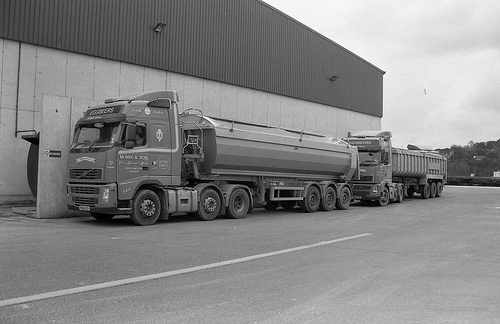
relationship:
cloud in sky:
[262, 0, 499, 150] [261, 1, 497, 150]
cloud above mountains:
[262, 0, 499, 150] [453, 144, 499, 174]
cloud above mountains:
[262, 0, 499, 150] [434, 141, 498, 188]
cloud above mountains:
[262, 0, 499, 150] [416, 132, 498, 179]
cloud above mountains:
[262, 0, 499, 150] [445, 136, 497, 177]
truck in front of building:
[65, 85, 357, 230] [2, 0, 386, 202]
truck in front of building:
[336, 129, 448, 204] [2, 0, 386, 202]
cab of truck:
[63, 91, 177, 219] [65, 85, 357, 230]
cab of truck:
[346, 132, 389, 202] [360, 135, 447, 201]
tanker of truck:
[177, 106, 361, 183] [65, 85, 357, 230]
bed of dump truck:
[394, 172, 445, 186] [346, 132, 451, 213]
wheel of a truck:
[129, 186, 162, 226] [65, 85, 357, 230]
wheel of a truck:
[197, 185, 220, 223] [65, 85, 357, 230]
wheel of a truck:
[229, 188, 251, 218] [65, 85, 357, 230]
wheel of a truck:
[300, 182, 322, 213] [65, 85, 357, 230]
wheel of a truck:
[322, 184, 337, 210] [65, 85, 357, 230]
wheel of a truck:
[197, 185, 220, 223] [68, 91, 355, 247]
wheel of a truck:
[337, 178, 364, 214] [70, 69, 418, 298]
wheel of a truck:
[377, 186, 392, 206] [348, 117, 445, 196]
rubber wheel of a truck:
[396, 182, 406, 200] [336, 129, 448, 204]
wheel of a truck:
[422, 183, 429, 198] [345, 130, 446, 205]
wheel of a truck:
[430, 181, 439, 195] [359, 124, 449, 213]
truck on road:
[336, 129, 449, 205] [2, 187, 498, 319]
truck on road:
[65, 85, 357, 230] [2, 187, 498, 319]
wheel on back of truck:
[295, 182, 322, 214] [65, 85, 357, 230]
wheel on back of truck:
[322, 184, 337, 213] [65, 85, 357, 230]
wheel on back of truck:
[337, 184, 352, 212] [65, 85, 357, 230]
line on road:
[66, 232, 299, 302] [145, 190, 493, 322]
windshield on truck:
[70, 121, 123, 143] [65, 85, 357, 230]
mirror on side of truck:
[381, 153, 390, 163] [345, 130, 446, 205]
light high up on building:
[330, 74, 338, 81] [2, 0, 386, 202]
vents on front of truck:
[63, 166, 110, 208] [62, 107, 363, 217]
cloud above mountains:
[262, 0, 499, 150] [404, 140, 498, 185]